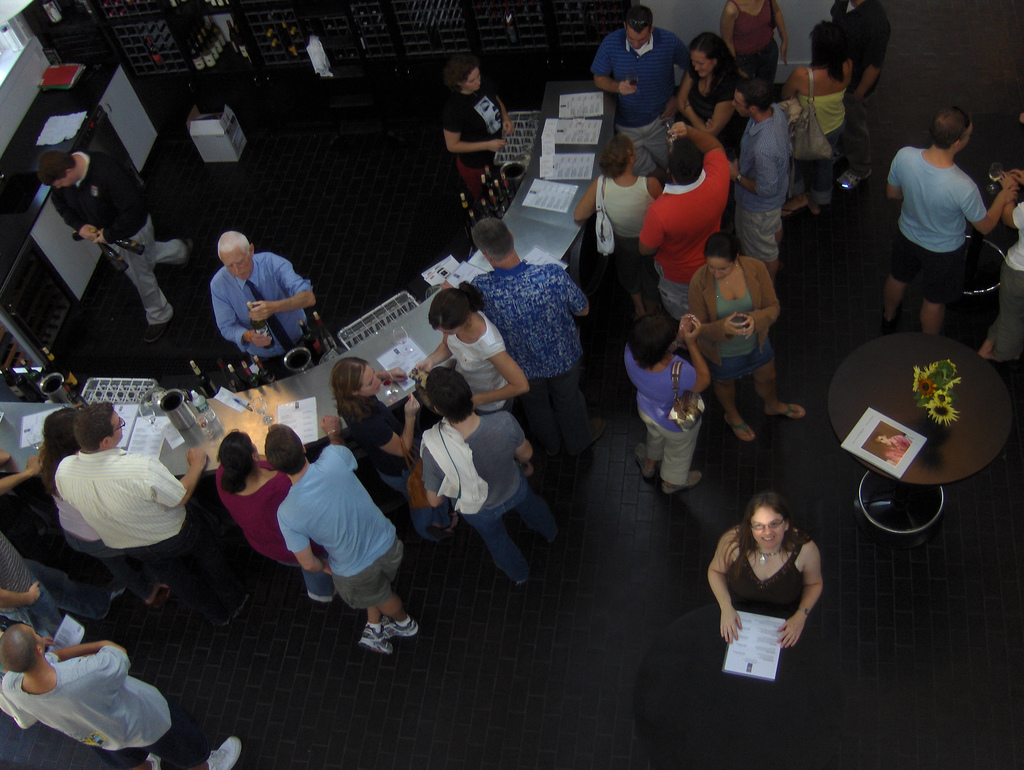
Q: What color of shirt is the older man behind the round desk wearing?
A: Blue.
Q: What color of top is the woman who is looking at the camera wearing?
A: Brown.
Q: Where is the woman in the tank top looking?
A: At the camera.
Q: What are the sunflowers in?
A: A vase.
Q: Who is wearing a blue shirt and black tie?
A: Bartender.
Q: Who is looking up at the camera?
A: A woman.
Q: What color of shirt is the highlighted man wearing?
A: Blue with white.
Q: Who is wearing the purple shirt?
A: A woman.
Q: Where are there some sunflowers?
A: Middle of table.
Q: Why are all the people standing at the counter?
A: Order drinks.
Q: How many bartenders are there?
A: 3.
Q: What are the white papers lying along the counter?
A: Menus.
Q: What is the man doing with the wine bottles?
A: Opening them.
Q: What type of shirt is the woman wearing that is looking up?
A: Tank top.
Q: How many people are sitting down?
A: None.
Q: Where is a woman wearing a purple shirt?
A: At counter next to man in blue shirt.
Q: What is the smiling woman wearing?
A: A tank top.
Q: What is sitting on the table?
A: Flowers.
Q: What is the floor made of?
A: Bricks.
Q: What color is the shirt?
A: Blue.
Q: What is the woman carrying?
A: A purse.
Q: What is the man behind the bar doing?
A: Opening a wine bottle.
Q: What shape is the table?
A: Round.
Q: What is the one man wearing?
A: A shirt and shorts.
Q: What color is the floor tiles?
A: Black.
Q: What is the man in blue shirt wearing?
A: Tie.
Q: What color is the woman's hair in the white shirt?
A: Brown.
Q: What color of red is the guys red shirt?
A: Bright red.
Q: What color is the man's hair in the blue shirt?
A: White.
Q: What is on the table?
A: Flowers.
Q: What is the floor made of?
A: Tile.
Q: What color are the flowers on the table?
A: Yellow.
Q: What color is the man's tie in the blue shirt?
A: Black.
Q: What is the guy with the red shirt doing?
A: Drinking.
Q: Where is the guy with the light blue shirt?
A: The bar.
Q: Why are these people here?
A: To drink.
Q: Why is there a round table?
A: For people to use.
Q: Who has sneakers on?
A: The guy with a light blue shirt.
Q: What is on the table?
A: Flowers and a picture.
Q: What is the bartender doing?
A: Opening a bottle.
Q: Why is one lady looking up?
A: She sees the camera.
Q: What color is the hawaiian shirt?
A: Blue.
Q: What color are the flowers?
A: Yellow and orange.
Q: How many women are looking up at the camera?
A: One.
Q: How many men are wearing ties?
A: One.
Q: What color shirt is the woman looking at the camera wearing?
A: Black.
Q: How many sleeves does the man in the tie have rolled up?
A: One.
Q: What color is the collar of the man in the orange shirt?
A: White.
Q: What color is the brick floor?
A: Black.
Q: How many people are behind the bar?
A: Three.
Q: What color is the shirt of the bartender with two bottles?
A: Black.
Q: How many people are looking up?
A: 1.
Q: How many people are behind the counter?
A: 3.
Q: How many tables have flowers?
A: 1.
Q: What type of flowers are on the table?
A: Sunflowers.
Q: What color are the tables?
A: Black.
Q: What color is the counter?
A: Gray.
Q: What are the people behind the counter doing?
A: Bartending.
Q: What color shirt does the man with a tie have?
A: Blue.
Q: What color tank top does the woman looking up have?
A: Black.